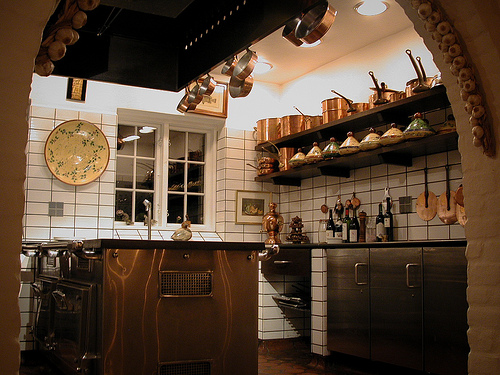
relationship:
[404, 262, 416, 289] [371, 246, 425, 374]
handle on front of cupboard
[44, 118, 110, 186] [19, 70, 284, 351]
plate hanging on wall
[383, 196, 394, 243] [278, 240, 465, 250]
bottle on top of counter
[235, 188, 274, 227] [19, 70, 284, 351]
picture hanging on wall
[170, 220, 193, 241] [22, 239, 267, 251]
knick knack on top of counter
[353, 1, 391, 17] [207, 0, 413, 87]
light recessed in ceiling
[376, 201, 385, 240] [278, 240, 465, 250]
bottle on top of counter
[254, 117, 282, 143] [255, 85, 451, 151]
pot on top of top shelf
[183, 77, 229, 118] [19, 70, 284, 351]
picture hanging on wall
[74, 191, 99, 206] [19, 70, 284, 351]
tile hanging on wall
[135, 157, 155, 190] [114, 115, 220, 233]
pane in middle of window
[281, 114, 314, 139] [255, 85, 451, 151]
pot on top of top shelf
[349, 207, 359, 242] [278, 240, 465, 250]
bottle on top of counter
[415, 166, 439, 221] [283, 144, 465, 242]
fan on side of back splash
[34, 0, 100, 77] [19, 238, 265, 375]
garlic hanging above stove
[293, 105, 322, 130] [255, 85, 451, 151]
pot sitting on top shelf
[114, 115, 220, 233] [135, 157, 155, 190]
window has pane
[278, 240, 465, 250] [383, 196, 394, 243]
counter has bottle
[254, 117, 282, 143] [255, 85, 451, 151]
pot lined up on top shelf